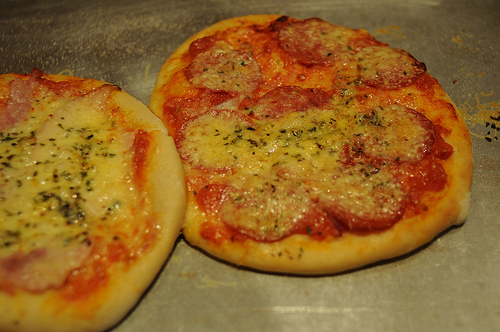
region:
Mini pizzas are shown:
[3, 12, 475, 328]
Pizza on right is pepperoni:
[145, 16, 472, 272]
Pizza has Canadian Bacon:
[2, 67, 189, 324]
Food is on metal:
[1, 2, 498, 330]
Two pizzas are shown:
[1, 15, 471, 330]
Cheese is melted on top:
[2, 19, 447, 329]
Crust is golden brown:
[148, 10, 474, 277]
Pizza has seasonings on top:
[0, 14, 469, 329]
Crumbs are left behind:
[1, 1, 498, 105]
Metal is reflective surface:
[113, 225, 498, 330]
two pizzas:
[9, 57, 484, 327]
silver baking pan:
[39, 6, 201, 82]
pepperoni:
[196, 31, 261, 103]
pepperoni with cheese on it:
[192, 27, 267, 118]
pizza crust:
[286, 237, 409, 292]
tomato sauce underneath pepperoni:
[399, 161, 474, 213]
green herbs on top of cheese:
[219, 127, 347, 148]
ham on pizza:
[1, 81, 56, 136]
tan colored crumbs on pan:
[34, 21, 201, 77]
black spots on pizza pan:
[478, 108, 498, 127]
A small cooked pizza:
[158, 12, 474, 273]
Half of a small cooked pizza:
[1, 71, 185, 330]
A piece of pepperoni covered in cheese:
[190, 43, 255, 96]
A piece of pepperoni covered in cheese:
[354, 104, 433, 161]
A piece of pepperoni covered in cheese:
[276, 17, 349, 64]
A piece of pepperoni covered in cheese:
[227, 174, 310, 241]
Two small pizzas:
[4, 12, 471, 330]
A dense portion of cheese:
[183, 110, 352, 174]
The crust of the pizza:
[105, 84, 187, 330]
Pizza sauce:
[263, 62, 329, 90]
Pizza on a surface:
[145, 7, 490, 287]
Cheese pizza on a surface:
[3, 59, 188, 330]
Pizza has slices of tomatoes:
[187, 9, 442, 251]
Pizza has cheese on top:
[144, 3, 484, 285]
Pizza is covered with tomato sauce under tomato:
[140, 5, 488, 292]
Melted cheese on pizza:
[5, 107, 130, 244]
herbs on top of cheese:
[1, 111, 113, 228]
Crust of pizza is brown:
[136, 9, 497, 280]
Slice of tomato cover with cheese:
[308, 159, 413, 234]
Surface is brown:
[7, 5, 498, 330]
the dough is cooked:
[142, 6, 462, 307]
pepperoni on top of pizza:
[197, 29, 430, 266]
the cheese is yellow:
[145, 26, 435, 291]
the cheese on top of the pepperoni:
[162, 34, 428, 249]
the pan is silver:
[60, 27, 160, 79]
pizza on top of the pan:
[146, 11, 478, 326]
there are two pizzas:
[5, 24, 497, 311]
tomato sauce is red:
[192, 39, 420, 252]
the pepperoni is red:
[189, 96, 279, 187]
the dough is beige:
[155, 31, 445, 312]